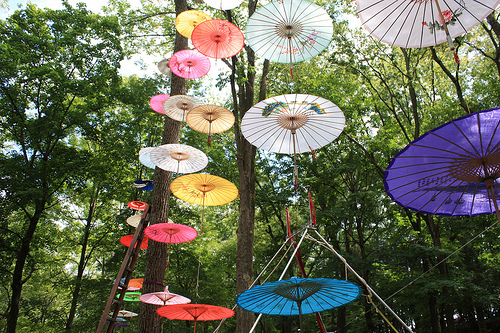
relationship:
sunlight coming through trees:
[114, 46, 159, 84] [3, 8, 124, 328]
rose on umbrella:
[425, 9, 464, 34] [350, 0, 499, 52]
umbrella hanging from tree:
[234, 273, 370, 321] [140, 17, 187, 330]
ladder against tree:
[94, 201, 150, 330] [140, 17, 187, 330]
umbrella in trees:
[141, 221, 200, 247] [3, 8, 124, 328]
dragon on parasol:
[260, 103, 328, 119] [229, 89, 357, 159]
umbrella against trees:
[141, 221, 200, 247] [3, 8, 124, 328]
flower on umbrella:
[425, 9, 464, 34] [350, 0, 499, 52]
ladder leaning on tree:
[94, 201, 150, 330] [140, 17, 187, 330]